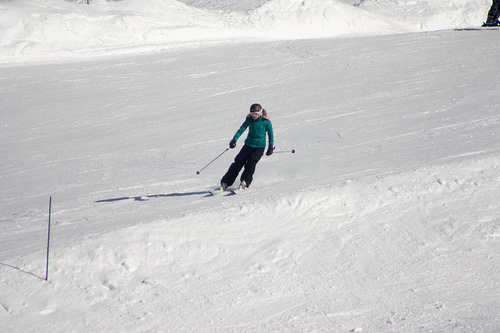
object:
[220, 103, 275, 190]
woman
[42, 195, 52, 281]
stick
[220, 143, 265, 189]
pant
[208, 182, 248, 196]
ski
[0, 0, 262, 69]
hill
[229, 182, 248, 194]
board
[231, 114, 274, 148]
sweater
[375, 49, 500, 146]
slope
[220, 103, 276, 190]
lady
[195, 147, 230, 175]
pole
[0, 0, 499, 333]
snow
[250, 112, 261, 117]
goggle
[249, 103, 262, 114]
helmet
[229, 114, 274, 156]
coat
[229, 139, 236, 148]
glove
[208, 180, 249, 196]
boot